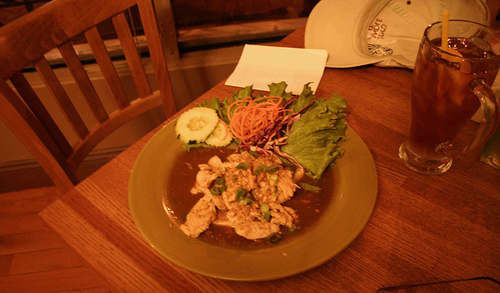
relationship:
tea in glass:
[420, 61, 456, 144] [404, 19, 498, 182]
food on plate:
[189, 100, 299, 239] [278, 240, 332, 284]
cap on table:
[297, 2, 428, 84] [341, 72, 398, 131]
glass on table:
[404, 19, 498, 182] [341, 72, 398, 131]